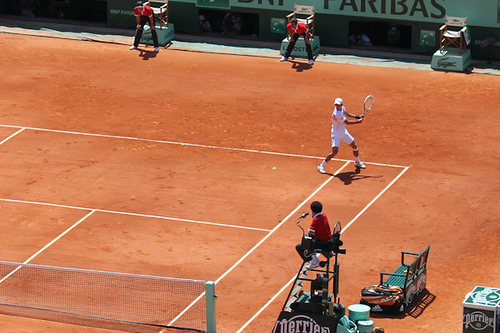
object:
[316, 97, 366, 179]
player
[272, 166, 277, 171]
ball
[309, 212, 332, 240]
shirt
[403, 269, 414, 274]
water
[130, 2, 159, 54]
person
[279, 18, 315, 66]
man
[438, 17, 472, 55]
seat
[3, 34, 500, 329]
court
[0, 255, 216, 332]
net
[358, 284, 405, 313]
bag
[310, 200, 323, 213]
hair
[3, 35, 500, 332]
dirt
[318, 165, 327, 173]
sneakers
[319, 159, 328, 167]
sock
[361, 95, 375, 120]
racket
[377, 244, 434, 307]
bench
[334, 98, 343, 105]
hat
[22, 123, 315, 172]
line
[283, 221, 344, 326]
chair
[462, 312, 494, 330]
logo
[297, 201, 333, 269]
commentator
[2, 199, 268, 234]
lines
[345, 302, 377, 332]
barrels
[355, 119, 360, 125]
wristband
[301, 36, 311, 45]
hands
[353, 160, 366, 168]
shoe